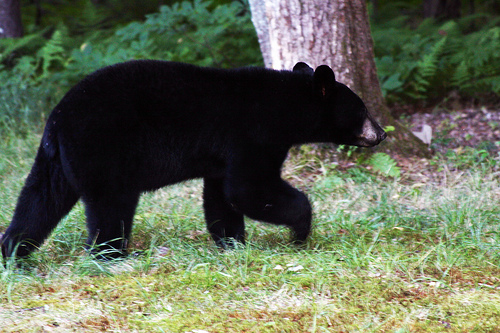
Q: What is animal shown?
A: Bear.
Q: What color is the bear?
A: Black.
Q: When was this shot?
A: Daytime.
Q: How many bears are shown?
A: 1.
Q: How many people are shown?
A: 0.